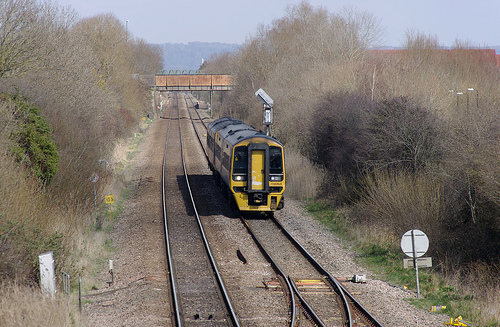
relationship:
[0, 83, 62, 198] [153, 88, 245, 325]
tree on left of tracks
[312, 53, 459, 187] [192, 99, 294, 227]
trees on right of train